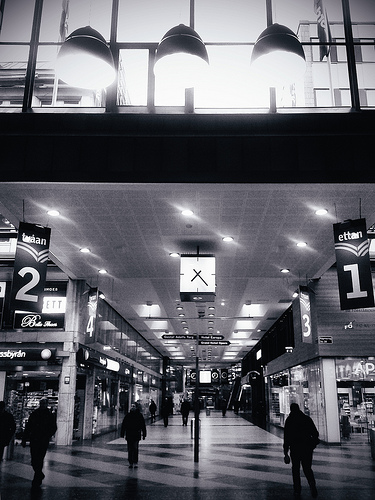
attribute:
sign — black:
[160, 328, 194, 342]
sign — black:
[197, 332, 226, 340]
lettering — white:
[200, 334, 223, 339]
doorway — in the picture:
[44, 359, 124, 434]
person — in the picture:
[276, 397, 321, 488]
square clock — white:
[177, 252, 219, 304]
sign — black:
[161, 332, 199, 340]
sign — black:
[198, 333, 224, 338]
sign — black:
[198, 341, 231, 345]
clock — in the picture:
[179, 251, 216, 293]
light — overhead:
[179, 315, 188, 326]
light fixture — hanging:
[249, 23, 307, 91]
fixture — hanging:
[53, 19, 312, 98]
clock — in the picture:
[176, 234, 220, 306]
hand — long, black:
[195, 269, 208, 286]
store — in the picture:
[258, 343, 374, 453]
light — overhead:
[216, 328, 219, 333]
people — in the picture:
[32, 369, 346, 499]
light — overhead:
[298, 240, 306, 247]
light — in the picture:
[243, 0, 311, 89]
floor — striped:
[144, 396, 275, 472]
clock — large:
[178, 256, 217, 298]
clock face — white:
[180, 257, 215, 292]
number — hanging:
[302, 308, 312, 339]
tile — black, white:
[215, 447, 281, 480]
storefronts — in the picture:
[4, 327, 185, 442]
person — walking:
[280, 398, 322, 498]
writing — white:
[163, 331, 198, 340]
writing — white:
[194, 333, 228, 342]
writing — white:
[193, 337, 229, 346]